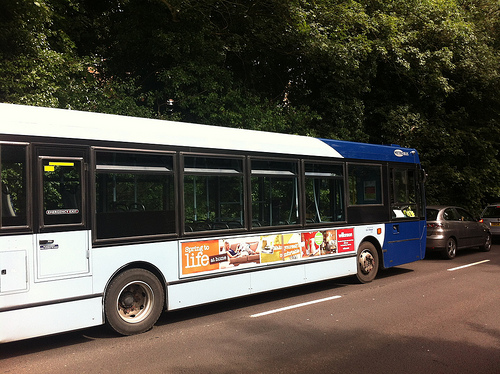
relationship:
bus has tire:
[20, 94, 455, 369] [102, 265, 165, 335]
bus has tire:
[20, 94, 455, 369] [355, 238, 381, 283]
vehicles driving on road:
[425, 201, 485, 259] [244, 282, 496, 339]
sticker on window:
[48, 160, 76, 165] [37, 155, 84, 230]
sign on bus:
[191, 223, 418, 284] [85, 109, 480, 304]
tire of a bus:
[356, 240, 380, 285] [0, 101, 430, 346]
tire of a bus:
[344, 229, 388, 283] [0, 101, 430, 346]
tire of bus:
[102, 265, 165, 335] [0, 101, 430, 346]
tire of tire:
[356, 240, 380, 285] [102, 265, 165, 335]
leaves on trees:
[16, 6, 491, 188] [10, 8, 484, 203]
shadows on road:
[236, 309, 493, 373] [2, 221, 480, 371]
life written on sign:
[183, 250, 210, 270] [181, 238, 219, 274]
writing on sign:
[336, 230, 351, 254] [338, 227, 355, 252]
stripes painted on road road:
[248, 243, 488, 366] [225, 292, 499, 367]